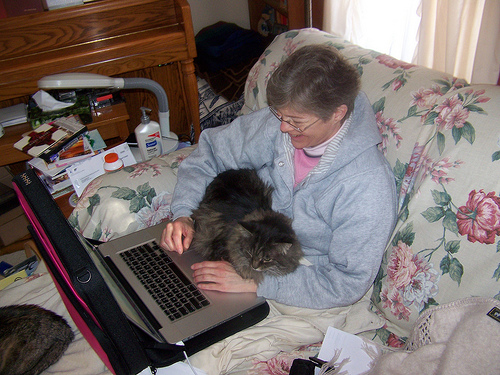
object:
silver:
[170, 320, 195, 331]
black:
[179, 294, 181, 297]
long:
[196, 210, 236, 234]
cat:
[200, 166, 297, 281]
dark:
[225, 178, 238, 189]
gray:
[231, 240, 237, 248]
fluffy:
[205, 229, 220, 242]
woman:
[242, 38, 392, 298]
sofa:
[82, 34, 497, 337]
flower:
[455, 190, 500, 249]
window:
[317, 0, 423, 53]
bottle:
[100, 152, 123, 172]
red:
[104, 153, 117, 162]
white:
[104, 163, 119, 167]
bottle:
[135, 106, 162, 159]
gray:
[132, 78, 162, 97]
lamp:
[33, 69, 180, 160]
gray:
[359, 264, 371, 271]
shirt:
[179, 116, 396, 264]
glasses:
[264, 104, 313, 137]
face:
[263, 93, 345, 155]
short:
[316, 63, 356, 108]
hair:
[260, 43, 358, 125]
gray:
[321, 86, 334, 95]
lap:
[127, 261, 377, 360]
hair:
[200, 185, 282, 257]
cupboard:
[250, 2, 313, 33]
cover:
[369, 51, 493, 356]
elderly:
[271, 45, 375, 205]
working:
[153, 121, 251, 350]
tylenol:
[103, 153, 126, 173]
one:
[101, 153, 125, 171]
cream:
[444, 319, 492, 373]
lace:
[412, 320, 433, 348]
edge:
[374, 343, 404, 368]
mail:
[74, 142, 139, 200]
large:
[2, 7, 199, 151]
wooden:
[100, 108, 127, 137]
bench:
[3, 100, 132, 151]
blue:
[311, 187, 320, 194]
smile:
[281, 132, 310, 141]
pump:
[140, 107, 153, 124]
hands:
[189, 251, 249, 294]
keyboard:
[106, 231, 217, 336]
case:
[13, 171, 140, 369]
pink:
[35, 224, 50, 244]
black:
[97, 291, 105, 300]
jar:
[131, 108, 170, 167]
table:
[5, 144, 190, 194]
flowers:
[430, 170, 454, 187]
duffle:
[194, 18, 265, 78]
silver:
[271, 112, 323, 133]